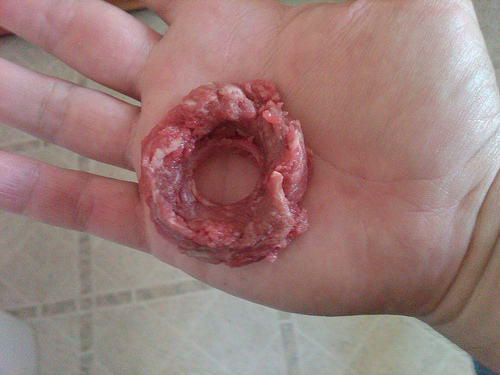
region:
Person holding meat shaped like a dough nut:
[106, 76, 331, 251]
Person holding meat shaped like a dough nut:
[226, 141, 302, 236]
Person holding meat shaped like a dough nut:
[120, 144, 317, 270]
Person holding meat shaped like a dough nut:
[117, 111, 218, 237]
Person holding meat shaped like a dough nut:
[214, 70, 309, 261]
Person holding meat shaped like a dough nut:
[132, 82, 310, 159]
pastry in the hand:
[123, 69, 333, 266]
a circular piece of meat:
[144, 86, 304, 258]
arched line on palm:
[314, 160, 452, 185]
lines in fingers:
[68, 177, 98, 232]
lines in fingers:
[18, 167, 44, 217]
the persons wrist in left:
[435, 262, 499, 353]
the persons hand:
[0, 0, 480, 317]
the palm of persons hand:
[255, 30, 434, 250]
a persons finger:
[0, 80, 123, 153]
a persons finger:
[0, 0, 162, 90]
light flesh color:
[363, 186, 471, 296]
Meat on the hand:
[163, 84, 302, 257]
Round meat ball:
[152, 80, 307, 253]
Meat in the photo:
[160, 79, 302, 241]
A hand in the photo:
[350, 172, 477, 286]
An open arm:
[333, 84, 433, 249]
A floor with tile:
[71, 266, 199, 349]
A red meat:
[168, 86, 324, 253]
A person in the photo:
[422, 216, 497, 316]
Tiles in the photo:
[113, 312, 230, 373]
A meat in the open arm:
[156, 99, 307, 236]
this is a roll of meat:
[113, 71, 335, 273]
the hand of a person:
[10, 2, 496, 345]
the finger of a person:
[4, 157, 149, 240]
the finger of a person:
[1, 64, 127, 169]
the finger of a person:
[23, 3, 155, 75]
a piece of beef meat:
[219, 202, 284, 277]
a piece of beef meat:
[176, 185, 233, 261]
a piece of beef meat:
[265, 108, 305, 197]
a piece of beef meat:
[190, 73, 253, 152]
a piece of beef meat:
[171, 96, 217, 154]